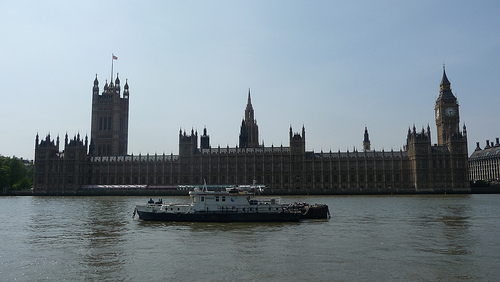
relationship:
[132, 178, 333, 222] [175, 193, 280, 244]
boat painted white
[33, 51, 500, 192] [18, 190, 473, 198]
building in road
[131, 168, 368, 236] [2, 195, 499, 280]
boat in water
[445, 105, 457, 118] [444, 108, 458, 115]
clock has face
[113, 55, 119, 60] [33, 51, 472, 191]
flag on building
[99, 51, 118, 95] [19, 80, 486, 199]
pole on building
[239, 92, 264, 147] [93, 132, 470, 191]
steeple on building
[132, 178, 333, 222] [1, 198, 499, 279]
boat on river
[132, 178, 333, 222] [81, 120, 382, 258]
boat in profile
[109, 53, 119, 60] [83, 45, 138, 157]
flag on tower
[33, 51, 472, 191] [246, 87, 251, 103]
building has spire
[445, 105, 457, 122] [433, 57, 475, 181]
clock on tower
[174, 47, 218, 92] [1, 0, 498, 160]
cloud in sky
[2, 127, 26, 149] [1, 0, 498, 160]
cloud in sky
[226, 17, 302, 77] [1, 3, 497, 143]
cloud in sky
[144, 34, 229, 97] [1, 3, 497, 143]
white clouds in sky